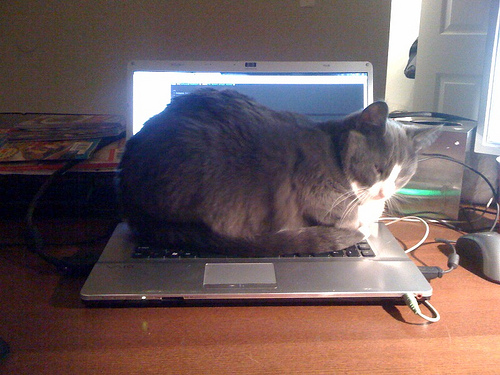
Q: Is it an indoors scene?
A: Yes, it is indoors.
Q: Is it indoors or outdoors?
A: It is indoors.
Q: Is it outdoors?
A: No, it is indoors.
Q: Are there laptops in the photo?
A: Yes, there is a laptop.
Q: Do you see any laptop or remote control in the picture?
A: Yes, there is a laptop.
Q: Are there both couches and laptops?
A: No, there is a laptop but no couches.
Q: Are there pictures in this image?
A: No, there are no pictures.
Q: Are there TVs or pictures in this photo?
A: No, there are no pictures or tvs.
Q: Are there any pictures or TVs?
A: No, there are no pictures or tvs.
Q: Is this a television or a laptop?
A: This is a laptop.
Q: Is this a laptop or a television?
A: This is a laptop.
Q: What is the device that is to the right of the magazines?
A: The device is a laptop.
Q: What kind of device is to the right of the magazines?
A: The device is a laptop.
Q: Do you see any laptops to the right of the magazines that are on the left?
A: Yes, there is a laptop to the right of the magazines.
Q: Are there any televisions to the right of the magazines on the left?
A: No, there is a laptop to the right of the magazines.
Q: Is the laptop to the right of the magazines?
A: Yes, the laptop is to the right of the magazines.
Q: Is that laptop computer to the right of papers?
A: No, the laptop computer is to the right of the magazines.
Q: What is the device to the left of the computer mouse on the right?
A: The device is a laptop.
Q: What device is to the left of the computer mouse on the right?
A: The device is a laptop.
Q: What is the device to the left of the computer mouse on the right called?
A: The device is a laptop.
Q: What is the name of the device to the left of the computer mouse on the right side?
A: The device is a laptop.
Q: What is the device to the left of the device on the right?
A: The device is a laptop.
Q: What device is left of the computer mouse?
A: The device is a laptop.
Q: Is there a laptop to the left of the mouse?
A: Yes, there is a laptop to the left of the mouse.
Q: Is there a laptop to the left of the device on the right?
A: Yes, there is a laptop to the left of the mouse.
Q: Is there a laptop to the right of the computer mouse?
A: No, the laptop is to the left of the computer mouse.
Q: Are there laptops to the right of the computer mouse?
A: No, the laptop is to the left of the computer mouse.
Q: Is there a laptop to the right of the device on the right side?
A: No, the laptop is to the left of the computer mouse.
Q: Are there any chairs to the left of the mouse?
A: No, there is a laptop to the left of the mouse.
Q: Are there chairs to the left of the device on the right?
A: No, there is a laptop to the left of the mouse.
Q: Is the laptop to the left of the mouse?
A: Yes, the laptop is to the left of the mouse.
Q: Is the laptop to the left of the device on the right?
A: Yes, the laptop is to the left of the mouse.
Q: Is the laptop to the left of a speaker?
A: No, the laptop is to the left of the mouse.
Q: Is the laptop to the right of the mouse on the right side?
A: No, the laptop is to the left of the computer mouse.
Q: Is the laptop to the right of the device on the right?
A: No, the laptop is to the left of the computer mouse.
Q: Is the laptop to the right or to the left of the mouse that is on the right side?
A: The laptop is to the left of the computer mouse.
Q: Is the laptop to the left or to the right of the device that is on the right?
A: The laptop is to the left of the computer mouse.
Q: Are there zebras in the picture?
A: No, there are no zebras.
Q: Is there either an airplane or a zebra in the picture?
A: No, there are no zebras or airplanes.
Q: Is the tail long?
A: Yes, the tail is long.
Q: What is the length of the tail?
A: The tail is long.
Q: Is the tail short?
A: No, the tail is long.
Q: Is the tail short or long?
A: The tail is long.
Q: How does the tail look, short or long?
A: The tail is long.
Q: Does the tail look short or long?
A: The tail is long.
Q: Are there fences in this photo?
A: No, there are no fences.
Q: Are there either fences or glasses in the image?
A: No, there are no fences or glasses.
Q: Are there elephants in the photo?
A: No, there are no elephants.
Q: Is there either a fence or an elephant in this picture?
A: No, there are no elephants or fences.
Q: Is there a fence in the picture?
A: No, there are no fences.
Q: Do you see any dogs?
A: No, there are no dogs.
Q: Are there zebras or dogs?
A: No, there are no dogs or zebras.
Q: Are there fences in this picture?
A: No, there are no fences.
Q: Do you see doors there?
A: Yes, there is a door.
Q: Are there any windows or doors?
A: Yes, there is a door.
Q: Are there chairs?
A: No, there are no chairs.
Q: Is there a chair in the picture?
A: No, there are no chairs.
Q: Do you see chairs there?
A: No, there are no chairs.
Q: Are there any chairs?
A: No, there are no chairs.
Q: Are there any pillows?
A: No, there are no pillows.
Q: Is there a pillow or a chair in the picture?
A: No, there are no pillows or chairs.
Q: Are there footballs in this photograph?
A: No, there are no footballs.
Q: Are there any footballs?
A: No, there are no footballs.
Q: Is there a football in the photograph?
A: No, there are no footballs.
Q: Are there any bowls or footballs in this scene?
A: No, there are no footballs or bowls.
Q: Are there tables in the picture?
A: Yes, there is a table.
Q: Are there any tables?
A: Yes, there is a table.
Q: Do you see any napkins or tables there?
A: Yes, there is a table.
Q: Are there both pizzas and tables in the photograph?
A: No, there is a table but no pizzas.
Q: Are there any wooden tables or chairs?
A: Yes, there is a wood table.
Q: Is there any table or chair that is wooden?
A: Yes, the table is wooden.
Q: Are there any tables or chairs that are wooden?
A: Yes, the table is wooden.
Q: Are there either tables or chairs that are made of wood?
A: Yes, the table is made of wood.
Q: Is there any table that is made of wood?
A: Yes, there is a table that is made of wood.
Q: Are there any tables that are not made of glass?
A: Yes, there is a table that is made of wood.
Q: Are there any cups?
A: No, there are no cups.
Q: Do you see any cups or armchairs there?
A: No, there are no cups or armchairs.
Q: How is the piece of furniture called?
A: The piece of furniture is a table.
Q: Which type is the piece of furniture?
A: The piece of furniture is a table.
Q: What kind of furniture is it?
A: The piece of furniture is a table.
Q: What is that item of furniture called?
A: This is a table.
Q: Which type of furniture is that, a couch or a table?
A: This is a table.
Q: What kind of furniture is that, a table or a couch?
A: This is a table.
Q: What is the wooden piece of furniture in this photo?
A: The piece of furniture is a table.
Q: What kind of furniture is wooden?
A: The furniture is a table.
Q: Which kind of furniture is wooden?
A: The furniture is a table.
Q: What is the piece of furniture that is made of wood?
A: The piece of furniture is a table.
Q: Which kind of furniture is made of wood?
A: The furniture is a table.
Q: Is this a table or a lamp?
A: This is a table.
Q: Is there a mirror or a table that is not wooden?
A: No, there is a table but it is wooden.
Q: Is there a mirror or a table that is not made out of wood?
A: No, there is a table but it is made of wood.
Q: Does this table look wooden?
A: Yes, the table is wooden.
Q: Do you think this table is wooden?
A: Yes, the table is wooden.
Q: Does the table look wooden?
A: Yes, the table is wooden.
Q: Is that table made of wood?
A: Yes, the table is made of wood.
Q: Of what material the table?
A: The table is made of wood.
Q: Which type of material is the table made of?
A: The table is made of wood.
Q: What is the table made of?
A: The table is made of wood.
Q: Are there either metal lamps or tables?
A: No, there is a table but it is wooden.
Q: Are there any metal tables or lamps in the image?
A: No, there is a table but it is wooden.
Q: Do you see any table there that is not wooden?
A: No, there is a table but it is wooden.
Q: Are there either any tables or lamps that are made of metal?
A: No, there is a table but it is made of wood.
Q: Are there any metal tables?
A: No, there is a table but it is made of wood.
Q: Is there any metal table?
A: No, there is a table but it is made of wood.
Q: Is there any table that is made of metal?
A: No, there is a table but it is made of wood.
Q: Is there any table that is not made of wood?
A: No, there is a table but it is made of wood.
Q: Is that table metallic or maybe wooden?
A: The table is wooden.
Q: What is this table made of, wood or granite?
A: The table is made of wood.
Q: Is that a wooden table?
A: Yes, that is a wooden table.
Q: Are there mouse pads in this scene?
A: Yes, there is a mouse pad.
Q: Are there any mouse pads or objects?
A: Yes, there is a mouse pad.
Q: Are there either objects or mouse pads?
A: Yes, there is a mouse pad.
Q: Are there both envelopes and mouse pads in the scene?
A: No, there is a mouse pad but no envelopes.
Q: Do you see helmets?
A: No, there are no helmets.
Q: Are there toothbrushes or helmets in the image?
A: No, there are no helmets or toothbrushes.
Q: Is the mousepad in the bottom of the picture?
A: Yes, the mousepad is in the bottom of the image.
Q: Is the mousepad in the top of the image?
A: No, the mousepad is in the bottom of the image.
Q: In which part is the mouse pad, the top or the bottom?
A: The mouse pad is in the bottom of the image.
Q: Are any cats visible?
A: Yes, there is a cat.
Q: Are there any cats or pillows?
A: Yes, there is a cat.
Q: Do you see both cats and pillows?
A: No, there is a cat but no pillows.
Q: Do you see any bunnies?
A: No, there are no bunnies.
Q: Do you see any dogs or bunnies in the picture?
A: No, there are no bunnies or dogs.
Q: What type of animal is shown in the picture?
A: The animal is a cat.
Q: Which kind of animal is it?
A: The animal is a cat.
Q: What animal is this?
A: This is a cat.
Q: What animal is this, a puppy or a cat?
A: This is a cat.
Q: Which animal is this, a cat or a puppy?
A: This is a cat.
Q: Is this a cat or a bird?
A: This is a cat.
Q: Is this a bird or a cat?
A: This is a cat.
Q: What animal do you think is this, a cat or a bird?
A: This is a cat.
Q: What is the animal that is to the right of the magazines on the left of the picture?
A: The animal is a cat.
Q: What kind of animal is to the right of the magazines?
A: The animal is a cat.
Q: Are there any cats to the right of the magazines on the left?
A: Yes, there is a cat to the right of the magazines.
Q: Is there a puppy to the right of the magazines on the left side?
A: No, there is a cat to the right of the magazines.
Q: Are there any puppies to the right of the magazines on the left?
A: No, there is a cat to the right of the magazines.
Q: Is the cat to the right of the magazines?
A: Yes, the cat is to the right of the magazines.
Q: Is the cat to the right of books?
A: No, the cat is to the right of the magazines.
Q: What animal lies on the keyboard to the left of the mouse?
A: The cat lies on the keyboard.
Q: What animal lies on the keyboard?
A: The cat lies on the keyboard.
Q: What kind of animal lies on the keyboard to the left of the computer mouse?
A: The animal is a cat.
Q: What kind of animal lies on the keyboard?
A: The animal is a cat.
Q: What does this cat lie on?
A: The cat lies on the keyboard.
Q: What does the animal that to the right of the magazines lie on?
A: The cat lies on the keyboard.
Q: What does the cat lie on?
A: The cat lies on the keyboard.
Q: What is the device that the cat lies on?
A: The device is a keyboard.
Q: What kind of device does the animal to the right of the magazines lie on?
A: The cat lies on the keyboard.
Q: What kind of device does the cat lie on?
A: The cat lies on the keyboard.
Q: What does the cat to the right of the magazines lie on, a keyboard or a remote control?
A: The cat lies on a keyboard.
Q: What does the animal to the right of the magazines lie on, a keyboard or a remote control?
A: The cat lies on a keyboard.